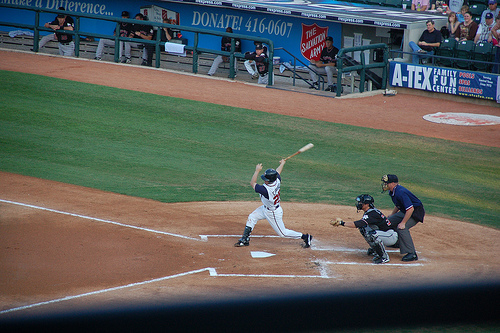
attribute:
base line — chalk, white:
[2, 195, 195, 248]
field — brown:
[3, 43, 499, 316]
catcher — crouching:
[331, 192, 394, 265]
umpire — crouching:
[383, 175, 432, 261]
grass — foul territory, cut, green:
[1, 71, 499, 231]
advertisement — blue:
[390, 63, 495, 99]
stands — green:
[2, 1, 499, 114]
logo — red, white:
[299, 19, 333, 63]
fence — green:
[1, 3, 268, 84]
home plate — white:
[251, 245, 272, 261]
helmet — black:
[259, 166, 276, 185]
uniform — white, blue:
[248, 184, 299, 240]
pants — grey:
[388, 215, 419, 254]